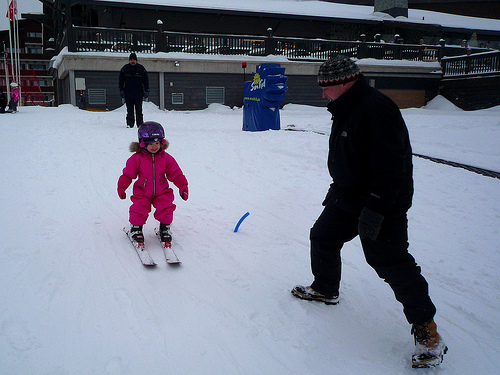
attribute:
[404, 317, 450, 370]
shoe — brown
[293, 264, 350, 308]
shoe — brown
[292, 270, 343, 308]
boot — brown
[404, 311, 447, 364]
boot — brown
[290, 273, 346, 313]
boot — brown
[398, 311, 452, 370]
boot — brown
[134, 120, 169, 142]
helmet — purple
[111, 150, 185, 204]
clothing — pink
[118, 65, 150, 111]
clothing — black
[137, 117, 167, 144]
safety helmet — purple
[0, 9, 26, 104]
poles — tall, metal, flag poles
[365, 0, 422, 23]
chimney — stone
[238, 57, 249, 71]
light — red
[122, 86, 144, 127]
pants — snow pants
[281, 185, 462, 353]
pants — snow pants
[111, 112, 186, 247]
girl — little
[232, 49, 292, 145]
sign — blue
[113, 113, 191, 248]
child — skiing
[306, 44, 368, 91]
beanie — grey, knitted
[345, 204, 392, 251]
gloves — knitted, grey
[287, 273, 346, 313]
snow boot — brown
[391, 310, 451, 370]
snow boot — brown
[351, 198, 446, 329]
snow pants — black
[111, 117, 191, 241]
girl — little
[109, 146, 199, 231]
snow suit — pink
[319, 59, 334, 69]
dot — white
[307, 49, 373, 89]
hat — winter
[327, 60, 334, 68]
dot — white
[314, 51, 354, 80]
hat — white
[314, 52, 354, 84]
hat — winter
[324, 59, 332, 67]
dot — white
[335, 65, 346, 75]
dot — white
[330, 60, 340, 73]
dot — white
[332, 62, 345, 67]
dot — white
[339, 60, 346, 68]
dot — white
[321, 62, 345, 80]
dots — white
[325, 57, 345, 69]
dots — white